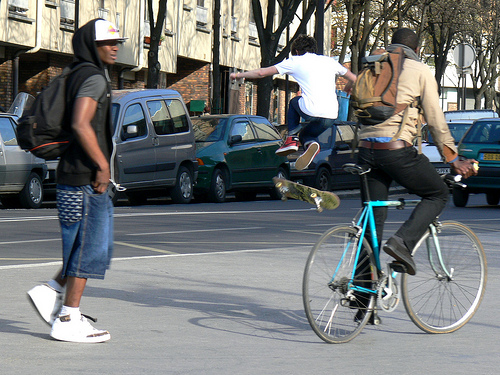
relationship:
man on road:
[24, 16, 130, 347] [2, 184, 495, 271]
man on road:
[230, 34, 359, 169] [2, 184, 495, 271]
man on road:
[354, 28, 482, 327] [2, 184, 495, 271]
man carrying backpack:
[24, 16, 130, 347] [10, 57, 102, 173]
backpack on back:
[324, 49, 446, 174] [57, 60, 87, 182]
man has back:
[24, 6, 136, 351] [57, 60, 87, 182]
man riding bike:
[329, 13, 450, 210] [297, 157, 492, 361]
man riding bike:
[354, 28, 482, 327] [302, 153, 484, 340]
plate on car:
[478, 150, 498, 162] [451, 104, 498, 204]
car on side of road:
[60, 76, 203, 199] [0, 166, 498, 374]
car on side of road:
[178, 94, 296, 205] [0, 166, 498, 374]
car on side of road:
[0, 90, 47, 209] [0, 166, 498, 374]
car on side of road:
[189, 113, 291, 202] [0, 166, 498, 374]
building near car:
[1, 2, 331, 127] [0, 112, 49, 204]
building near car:
[1, 2, 331, 127] [106, 88, 199, 201]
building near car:
[1, 2, 331, 127] [193, 114, 287, 201]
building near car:
[1, 2, 331, 127] [278, 122, 365, 193]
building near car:
[1, 2, 331, 127] [423, 107, 496, 195]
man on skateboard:
[230, 34, 356, 171] [272, 178, 341, 210]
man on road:
[24, 16, 130, 347] [0, 195, 499, 374]